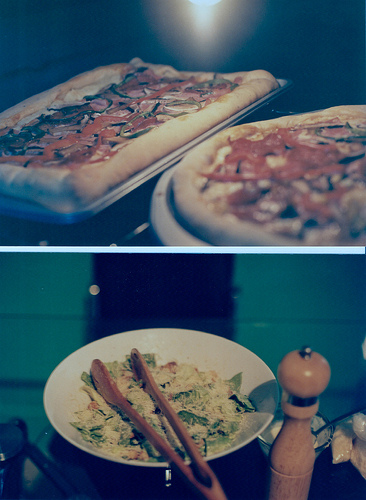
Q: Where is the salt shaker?
A: Near the plate.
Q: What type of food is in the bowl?
A: Salad.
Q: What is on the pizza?
A: Peppers and onions.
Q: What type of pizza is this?
A: Thick crust.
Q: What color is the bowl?
A: White.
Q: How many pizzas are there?
A: Two.